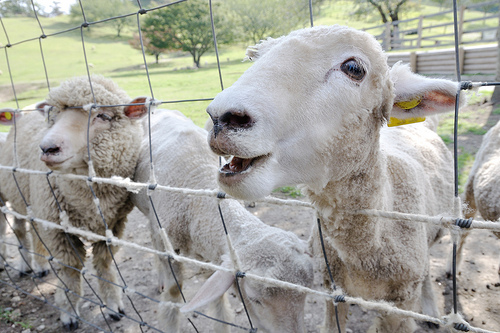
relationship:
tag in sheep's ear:
[383, 94, 424, 128] [389, 64, 467, 122]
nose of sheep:
[208, 104, 257, 130] [207, 27, 464, 331]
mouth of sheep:
[213, 148, 268, 176] [207, 27, 464, 331]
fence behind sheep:
[356, 1, 496, 81] [207, 27, 464, 331]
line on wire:
[216, 192, 226, 233] [2, 3, 495, 329]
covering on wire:
[246, 271, 326, 299] [2, 3, 495, 329]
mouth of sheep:
[211, 146, 270, 180] [207, 27, 464, 331]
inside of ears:
[387, 90, 456, 110] [383, 62, 463, 119]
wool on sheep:
[273, 81, 358, 160] [207, 27, 464, 331]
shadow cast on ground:
[104, 53, 249, 74] [2, 14, 497, 328]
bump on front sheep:
[281, 35, 326, 54] [207, 27, 464, 331]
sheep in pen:
[207, 27, 464, 331] [0, 0, 496, 331]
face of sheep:
[208, 37, 376, 186] [207, 27, 464, 331]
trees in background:
[94, 50, 182, 73] [18, 102, 364, 150]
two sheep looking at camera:
[34, 50, 344, 220] [97, 215, 147, 247]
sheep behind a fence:
[26, 68, 406, 263] [160, 265, 216, 322]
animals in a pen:
[17, 62, 493, 296] [162, 99, 209, 114]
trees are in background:
[115, 51, 193, 62] [29, 128, 494, 293]